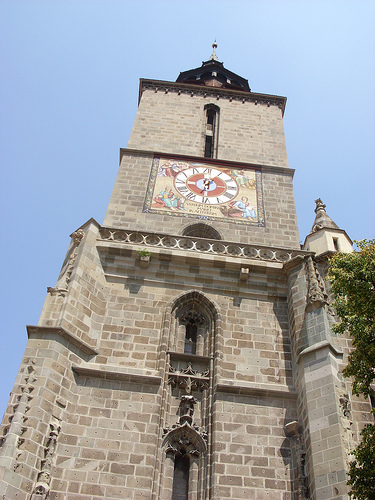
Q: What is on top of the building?
A: A tricolor clock.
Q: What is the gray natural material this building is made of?
A: Stone.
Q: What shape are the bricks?
A: Rectangle.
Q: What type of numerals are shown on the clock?
A: Roman.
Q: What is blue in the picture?
A: The sky.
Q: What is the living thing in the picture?
A: Tree.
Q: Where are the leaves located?
A: On the tree.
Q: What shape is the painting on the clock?
A: Square.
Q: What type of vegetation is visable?
A: A tree.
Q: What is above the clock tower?
A: The sky.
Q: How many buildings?
A: 1.